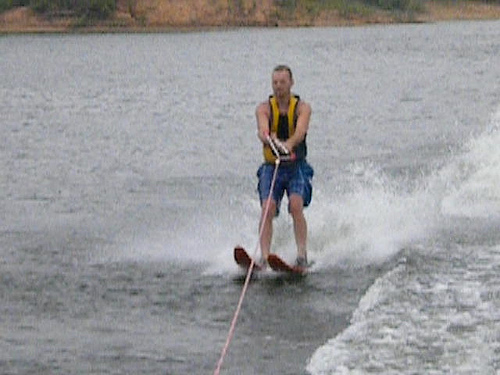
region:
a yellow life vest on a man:
[260, 92, 307, 164]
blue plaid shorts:
[257, 154, 314, 204]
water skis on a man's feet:
[232, 242, 317, 277]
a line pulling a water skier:
[203, 126, 291, 371]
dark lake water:
[0, 20, 495, 371]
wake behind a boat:
[310, 250, 487, 370]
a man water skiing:
[230, 60, 321, 288]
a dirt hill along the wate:
[1, 1, 498, 35]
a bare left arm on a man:
[281, 97, 312, 155]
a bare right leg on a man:
[257, 195, 279, 267]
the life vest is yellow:
[251, 73, 322, 173]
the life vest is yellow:
[206, 62, 358, 322]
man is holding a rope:
[180, 42, 402, 372]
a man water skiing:
[231, 56, 322, 277]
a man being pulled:
[227, 279, 254, 344]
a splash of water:
[352, 185, 442, 245]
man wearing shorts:
[282, 169, 306, 192]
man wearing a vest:
[271, 103, 298, 140]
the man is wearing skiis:
[267, 248, 291, 270]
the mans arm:
[294, 114, 310, 133]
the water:
[39, 125, 181, 250]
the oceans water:
[327, 30, 460, 107]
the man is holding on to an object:
[259, 130, 292, 160]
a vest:
[265, 96, 297, 127]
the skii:
[263, 248, 288, 282]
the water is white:
[334, 186, 434, 251]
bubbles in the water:
[330, 318, 382, 356]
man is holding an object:
[262, 128, 295, 158]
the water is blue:
[45, 76, 165, 178]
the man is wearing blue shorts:
[283, 165, 305, 194]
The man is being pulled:
[241, 244, 265, 280]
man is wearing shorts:
[284, 166, 309, 191]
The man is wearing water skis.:
[212, 43, 347, 311]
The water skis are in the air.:
[214, 53, 347, 305]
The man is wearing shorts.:
[209, 56, 334, 292]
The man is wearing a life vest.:
[211, 51, 329, 313]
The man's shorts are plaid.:
[216, 55, 340, 292]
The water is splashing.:
[1, 21, 499, 373]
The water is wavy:
[3, 29, 499, 374]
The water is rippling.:
[2, 26, 497, 373]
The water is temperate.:
[1, 28, 498, 373]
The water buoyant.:
[0, 25, 499, 373]